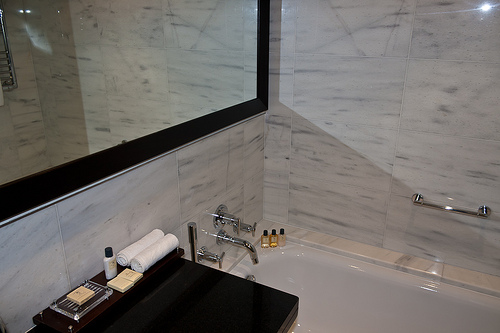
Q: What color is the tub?
A: White.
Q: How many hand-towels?
A: Two.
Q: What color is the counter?
A: Black.